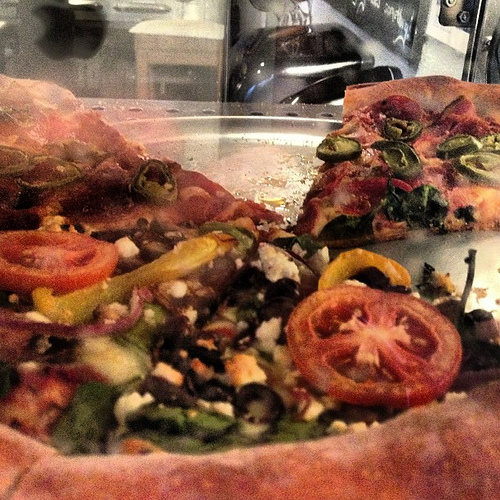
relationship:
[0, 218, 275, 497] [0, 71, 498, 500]
slice of pizza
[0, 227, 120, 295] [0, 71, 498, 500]
tomato on pizza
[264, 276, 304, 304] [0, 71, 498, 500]
olive slice on pizza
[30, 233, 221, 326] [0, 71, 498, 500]
pepper on pizza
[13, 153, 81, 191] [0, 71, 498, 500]
pepper on pizza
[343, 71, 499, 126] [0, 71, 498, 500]
crust of pizza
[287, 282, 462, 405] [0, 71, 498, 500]
tomato on pizza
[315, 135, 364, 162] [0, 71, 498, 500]
chili on pizza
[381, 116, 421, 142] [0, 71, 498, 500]
chili on pizza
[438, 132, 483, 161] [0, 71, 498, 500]
chili on pizza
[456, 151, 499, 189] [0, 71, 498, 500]
chili on pizza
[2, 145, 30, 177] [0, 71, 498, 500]
chili on pizza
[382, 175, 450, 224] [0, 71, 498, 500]
spinach on pizza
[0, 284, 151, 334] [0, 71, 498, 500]
onion on pizza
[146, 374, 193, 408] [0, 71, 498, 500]
olive on pizza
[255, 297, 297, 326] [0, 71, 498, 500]
olive on pizza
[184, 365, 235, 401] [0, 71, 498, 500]
olive on pizza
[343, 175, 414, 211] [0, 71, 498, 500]
meat on pizza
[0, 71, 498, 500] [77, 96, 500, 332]
pizza on plate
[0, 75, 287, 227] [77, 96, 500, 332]
slice on plate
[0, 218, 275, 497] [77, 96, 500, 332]
slice on plate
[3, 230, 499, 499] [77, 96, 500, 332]
slice on plate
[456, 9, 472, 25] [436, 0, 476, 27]
nut on plate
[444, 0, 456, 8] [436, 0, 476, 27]
nut on plate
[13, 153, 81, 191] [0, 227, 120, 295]
pepper next to tomato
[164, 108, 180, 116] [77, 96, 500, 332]
spot on plate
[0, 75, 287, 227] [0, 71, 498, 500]
slice of pizza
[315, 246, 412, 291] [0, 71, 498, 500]
vegetable on pizza